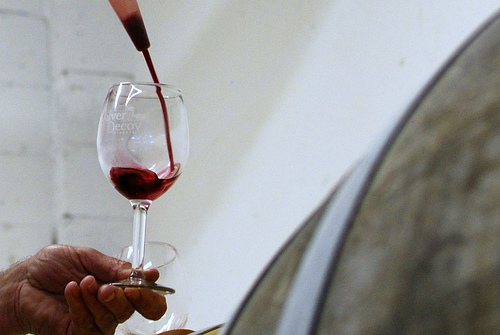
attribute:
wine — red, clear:
[110, 10, 191, 173]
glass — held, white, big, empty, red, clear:
[99, 75, 185, 207]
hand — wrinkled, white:
[10, 223, 180, 332]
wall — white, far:
[214, 8, 288, 67]